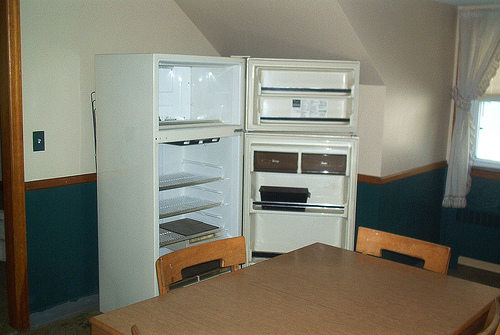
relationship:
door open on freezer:
[244, 56, 362, 133] [156, 55, 244, 132]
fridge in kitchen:
[93, 51, 361, 314] [0, 0, 498, 332]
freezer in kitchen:
[156, 55, 244, 132] [0, 0, 498, 332]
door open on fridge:
[239, 130, 361, 267] [93, 51, 361, 314]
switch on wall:
[17, 127, 55, 169] [30, 20, 75, 99]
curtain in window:
[437, 3, 499, 209] [470, 67, 498, 168]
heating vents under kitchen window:
[432, 201, 499, 263] [472, 99, 498, 163]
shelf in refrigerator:
[160, 172, 221, 191] [92, 46, 362, 313]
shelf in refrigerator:
[154, 197, 219, 223] [92, 46, 362, 313]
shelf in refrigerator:
[157, 216, 218, 249] [92, 46, 362, 313]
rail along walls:
[24, 161, 498, 191] [25, 2, 498, 312]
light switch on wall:
[36, 136, 40, 146] [43, 5, 454, 173]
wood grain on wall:
[25, 169, 100, 188] [23, 3, 92, 127]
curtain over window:
[428, 38, 478, 275] [453, 91, 497, 184]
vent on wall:
[453, 204, 498, 230] [40, 20, 85, 53]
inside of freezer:
[159, 66, 239, 125] [153, 64, 242, 126]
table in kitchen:
[86, 237, 498, 333] [0, 0, 496, 333]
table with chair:
[89, 242, 500, 334] [348, 210, 465, 276]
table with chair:
[89, 242, 500, 334] [142, 232, 264, 302]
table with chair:
[89, 242, 500, 334] [121, 312, 139, 333]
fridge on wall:
[93, 48, 365, 302] [27, 5, 245, 289]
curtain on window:
[437, 3, 499, 209] [448, 6, 481, 176]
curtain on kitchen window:
[437, 3, 499, 209] [451, 55, 498, 159]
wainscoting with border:
[38, 185, 85, 293] [362, 157, 451, 185]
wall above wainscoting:
[23, 3, 92, 127] [21, 178, 100, 302]